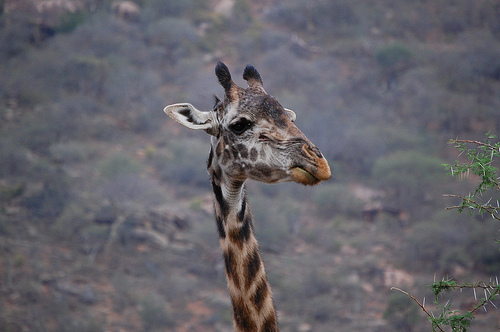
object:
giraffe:
[163, 54, 350, 329]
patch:
[221, 183, 243, 228]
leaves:
[439, 127, 499, 218]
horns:
[211, 58, 267, 96]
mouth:
[283, 154, 332, 187]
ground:
[373, 181, 410, 224]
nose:
[297, 136, 334, 168]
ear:
[162, 102, 216, 130]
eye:
[227, 116, 255, 136]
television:
[162, 60, 333, 197]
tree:
[422, 113, 482, 330]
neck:
[208, 179, 278, 328]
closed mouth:
[288, 156, 332, 187]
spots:
[216, 195, 276, 327]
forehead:
[219, 92, 275, 109]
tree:
[429, 86, 498, 323]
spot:
[236, 239, 266, 295]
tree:
[426, 91, 497, 331]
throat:
[204, 181, 293, 331]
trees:
[408, 67, 498, 330]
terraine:
[96, 6, 343, 87]